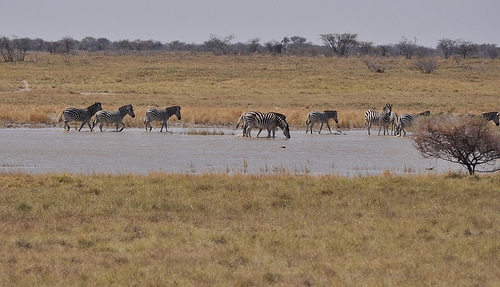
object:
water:
[71, 138, 257, 163]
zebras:
[144, 105, 182, 132]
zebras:
[90, 104, 135, 132]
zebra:
[235, 111, 291, 139]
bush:
[410, 108, 499, 176]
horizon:
[0, 32, 500, 57]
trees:
[316, 32, 357, 57]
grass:
[1, 49, 500, 96]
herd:
[56, 101, 499, 139]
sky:
[0, 0, 500, 34]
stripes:
[255, 113, 272, 125]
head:
[171, 105, 181, 120]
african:
[0, 0, 494, 286]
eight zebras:
[59, 102, 103, 132]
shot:
[0, 34, 497, 240]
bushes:
[410, 54, 442, 73]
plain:
[0, 55, 499, 102]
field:
[0, 45, 500, 100]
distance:
[47, 36, 193, 56]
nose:
[179, 118, 182, 119]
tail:
[235, 115, 243, 130]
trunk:
[466, 163, 473, 175]